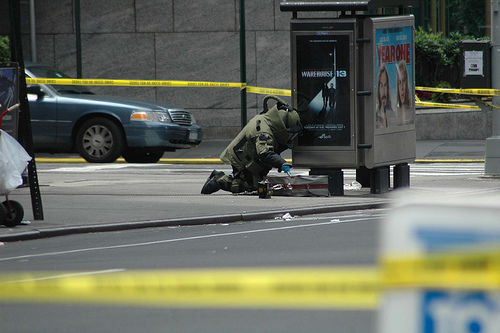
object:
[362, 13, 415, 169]
board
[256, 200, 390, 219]
corner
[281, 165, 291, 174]
hand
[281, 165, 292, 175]
glove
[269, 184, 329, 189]
red line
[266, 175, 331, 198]
package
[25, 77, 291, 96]
ribbon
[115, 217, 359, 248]
line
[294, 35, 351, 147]
poster ad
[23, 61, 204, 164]
car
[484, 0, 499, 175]
utility pole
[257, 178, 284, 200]
tools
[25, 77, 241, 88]
black letters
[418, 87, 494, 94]
black letters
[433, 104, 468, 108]
black letters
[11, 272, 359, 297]
black letters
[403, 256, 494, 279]
black letters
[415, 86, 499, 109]
ribbon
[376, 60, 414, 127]
people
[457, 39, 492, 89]
board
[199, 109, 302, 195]
man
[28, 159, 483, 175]
road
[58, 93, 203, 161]
front end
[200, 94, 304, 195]
clothes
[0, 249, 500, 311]
caution tape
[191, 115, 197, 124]
light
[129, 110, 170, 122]
headlight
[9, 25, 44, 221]
iron rod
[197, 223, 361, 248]
road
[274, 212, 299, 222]
litter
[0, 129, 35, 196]
garbage bag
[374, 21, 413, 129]
ads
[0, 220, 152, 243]
curb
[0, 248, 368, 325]
floor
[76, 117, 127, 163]
tire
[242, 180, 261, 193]
knees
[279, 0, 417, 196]
kiosk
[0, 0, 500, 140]
building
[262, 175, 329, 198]
bomb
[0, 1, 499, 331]
area